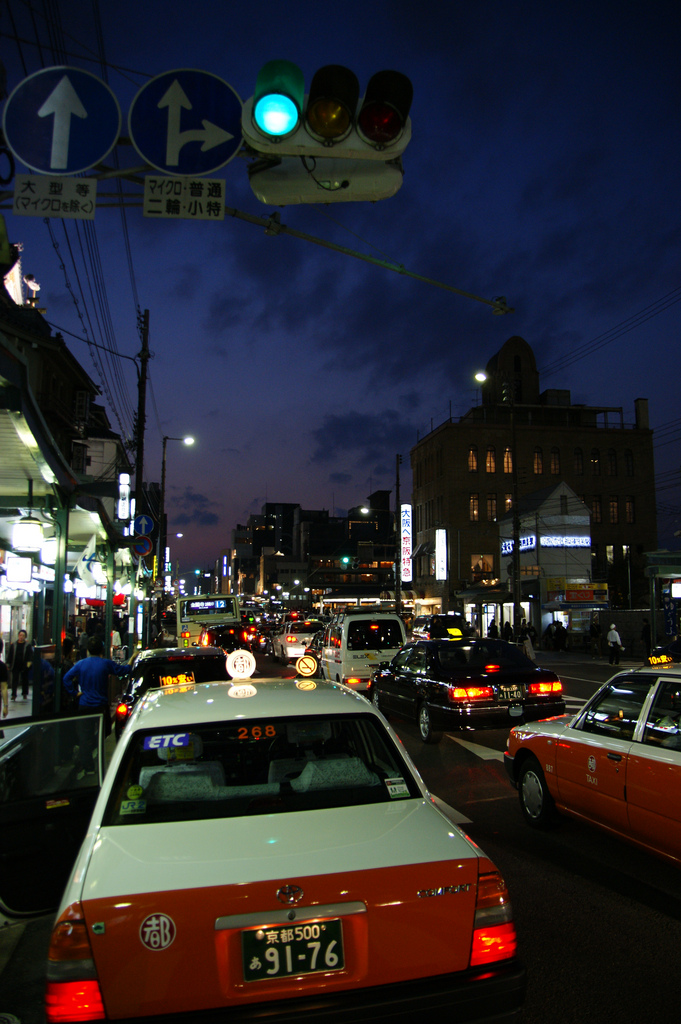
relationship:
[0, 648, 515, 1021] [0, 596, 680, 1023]
car on street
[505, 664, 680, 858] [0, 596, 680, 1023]
car on street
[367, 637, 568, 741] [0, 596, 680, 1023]
car on street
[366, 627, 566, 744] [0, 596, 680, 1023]
car on street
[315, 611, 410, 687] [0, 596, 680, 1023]
car on street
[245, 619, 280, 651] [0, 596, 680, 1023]
car on street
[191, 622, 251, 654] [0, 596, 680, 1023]
car on street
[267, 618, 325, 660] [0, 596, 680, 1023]
car on street